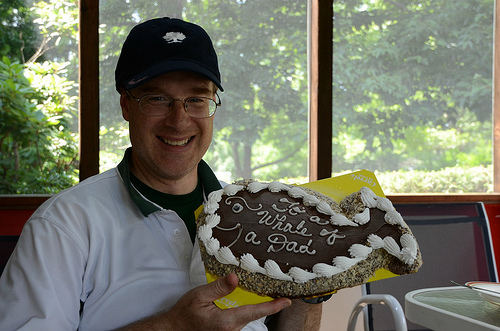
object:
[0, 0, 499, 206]
windows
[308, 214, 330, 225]
word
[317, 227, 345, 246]
word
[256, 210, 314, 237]
word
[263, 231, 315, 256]
word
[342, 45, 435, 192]
ground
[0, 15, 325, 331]
man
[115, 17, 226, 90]
hat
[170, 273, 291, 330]
hands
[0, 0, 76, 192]
bushes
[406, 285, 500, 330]
plate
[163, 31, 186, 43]
logo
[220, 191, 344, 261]
decorations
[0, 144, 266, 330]
white shirt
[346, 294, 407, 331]
white chair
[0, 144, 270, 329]
shirt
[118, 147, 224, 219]
collar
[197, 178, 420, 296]
cake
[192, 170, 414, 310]
plate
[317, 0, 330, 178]
frame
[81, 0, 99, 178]
frame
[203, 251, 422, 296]
almonds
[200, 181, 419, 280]
frosting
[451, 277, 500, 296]
silverware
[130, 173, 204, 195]
necklace